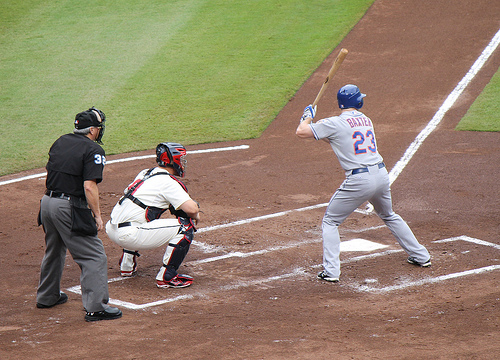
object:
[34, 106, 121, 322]
man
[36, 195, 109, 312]
gray pants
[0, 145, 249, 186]
white line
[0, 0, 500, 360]
field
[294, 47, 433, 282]
man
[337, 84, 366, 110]
blue helmet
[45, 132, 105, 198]
black shirt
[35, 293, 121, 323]
black shoes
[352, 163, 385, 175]
blue belt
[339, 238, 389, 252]
white base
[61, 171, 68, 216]
gray and black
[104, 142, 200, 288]
man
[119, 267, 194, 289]
red black sneakers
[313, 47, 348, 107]
bat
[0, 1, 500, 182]
grass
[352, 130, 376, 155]
number 23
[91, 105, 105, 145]
face mask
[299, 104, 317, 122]
blue white gloves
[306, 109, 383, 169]
gray jersey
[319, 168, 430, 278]
gray pants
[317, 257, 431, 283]
tennis shoes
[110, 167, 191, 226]
white shirt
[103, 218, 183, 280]
white pants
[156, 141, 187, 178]
mask